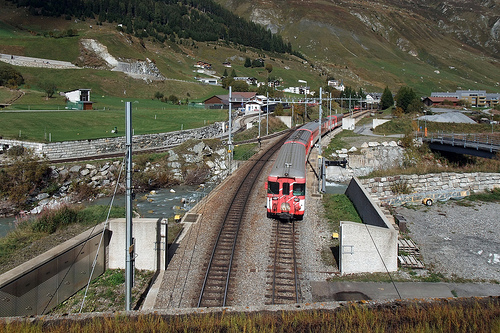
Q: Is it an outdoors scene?
A: Yes, it is outdoors.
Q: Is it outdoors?
A: Yes, it is outdoors.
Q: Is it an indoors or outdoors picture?
A: It is outdoors.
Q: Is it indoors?
A: No, it is outdoors.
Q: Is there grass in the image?
A: Yes, there is grass.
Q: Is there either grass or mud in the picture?
A: Yes, there is grass.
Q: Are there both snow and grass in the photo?
A: No, there is grass but no snow.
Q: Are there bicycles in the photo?
A: No, there are no bicycles.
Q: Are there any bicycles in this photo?
A: No, there are no bicycles.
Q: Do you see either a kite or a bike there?
A: No, there are no bikes or kites.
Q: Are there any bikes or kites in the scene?
A: No, there are no bikes or kites.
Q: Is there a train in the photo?
A: Yes, there is a train.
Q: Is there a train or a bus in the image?
A: Yes, there is a train.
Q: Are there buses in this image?
A: No, there are no buses.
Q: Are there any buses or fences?
A: No, there are no buses or fences.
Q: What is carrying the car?
A: The train is carrying the car.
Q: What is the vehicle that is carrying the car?
A: The vehicle is a train.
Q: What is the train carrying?
A: The train is carrying a car.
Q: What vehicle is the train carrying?
A: The train is carrying a car.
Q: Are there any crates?
A: No, there are no crates.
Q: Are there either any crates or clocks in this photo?
A: No, there are no crates or clocks.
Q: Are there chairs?
A: No, there are no chairs.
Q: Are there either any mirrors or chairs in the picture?
A: No, there are no chairs or mirrors.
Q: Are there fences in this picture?
A: No, there are no fences.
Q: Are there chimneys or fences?
A: No, there are no fences or chimneys.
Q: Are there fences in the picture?
A: No, there are no fences.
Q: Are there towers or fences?
A: No, there are no fences or towers.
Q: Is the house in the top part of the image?
A: Yes, the house is in the top of the image.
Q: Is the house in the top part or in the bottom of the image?
A: The house is in the top of the image.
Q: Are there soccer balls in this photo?
A: No, there are no soccer balls.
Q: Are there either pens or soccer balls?
A: No, there are no soccer balls or pens.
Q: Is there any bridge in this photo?
A: Yes, there is a bridge.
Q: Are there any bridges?
A: Yes, there is a bridge.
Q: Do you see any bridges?
A: Yes, there is a bridge.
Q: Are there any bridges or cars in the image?
A: Yes, there is a bridge.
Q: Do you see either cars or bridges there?
A: Yes, there is a bridge.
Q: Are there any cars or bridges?
A: Yes, there is a bridge.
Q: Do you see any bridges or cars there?
A: Yes, there is a bridge.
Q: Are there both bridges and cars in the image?
A: Yes, there are both a bridge and a car.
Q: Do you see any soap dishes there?
A: No, there are no soap dishes.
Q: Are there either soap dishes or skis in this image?
A: No, there are no soap dishes or skis.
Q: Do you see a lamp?
A: No, there are no lamps.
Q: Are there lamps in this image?
A: No, there are no lamps.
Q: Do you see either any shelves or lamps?
A: No, there are no lamps or shelves.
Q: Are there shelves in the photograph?
A: No, there are no shelves.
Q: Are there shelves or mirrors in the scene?
A: No, there are no shelves or mirrors.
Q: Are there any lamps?
A: No, there are no lamps.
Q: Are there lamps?
A: No, there are no lamps.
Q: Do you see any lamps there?
A: No, there are no lamps.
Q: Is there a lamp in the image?
A: No, there are no lamps.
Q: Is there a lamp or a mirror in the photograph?
A: No, there are no lamps or mirrors.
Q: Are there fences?
A: No, there are no fences.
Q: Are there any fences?
A: No, there are no fences.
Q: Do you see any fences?
A: No, there are no fences.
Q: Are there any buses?
A: No, there are no buses.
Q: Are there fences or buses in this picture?
A: No, there are no buses or fences.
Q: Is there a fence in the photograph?
A: No, there are no fences.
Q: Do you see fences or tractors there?
A: No, there are no fences or tractors.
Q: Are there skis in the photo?
A: No, there are no skis.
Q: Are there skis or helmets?
A: No, there are no skis or helmets.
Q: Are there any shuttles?
A: No, there are no shuttles.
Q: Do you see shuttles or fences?
A: No, there are no shuttles or fences.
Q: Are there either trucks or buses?
A: No, there are no buses or trucks.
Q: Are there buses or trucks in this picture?
A: No, there are no buses or trucks.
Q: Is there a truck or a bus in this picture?
A: No, there are no buses or trucks.